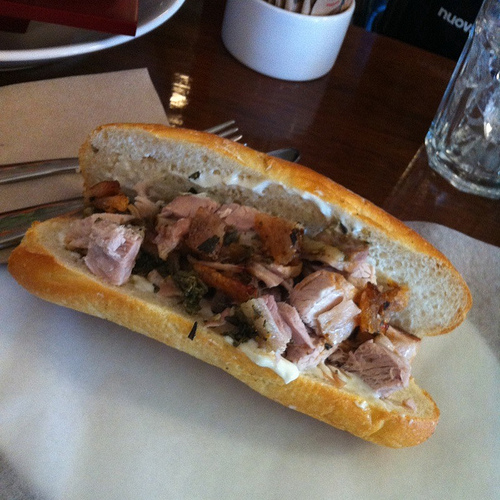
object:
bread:
[76, 122, 472, 342]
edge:
[31, 249, 394, 451]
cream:
[168, 166, 221, 196]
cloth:
[0, 62, 174, 263]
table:
[0, 0, 498, 497]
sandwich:
[9, 124, 473, 447]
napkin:
[0, 214, 498, 498]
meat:
[340, 341, 411, 395]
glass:
[419, 1, 500, 199]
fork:
[0, 117, 251, 185]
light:
[165, 69, 195, 129]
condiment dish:
[217, 1, 354, 85]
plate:
[0, 0, 181, 60]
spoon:
[0, 145, 300, 248]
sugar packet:
[301, 0, 313, 18]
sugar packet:
[287, 0, 302, 16]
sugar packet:
[309, 1, 344, 16]